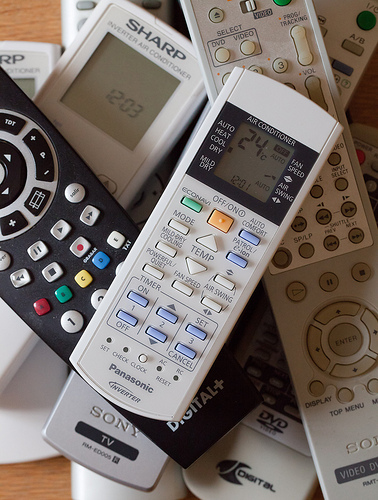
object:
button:
[355, 10, 376, 29]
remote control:
[311, 1, 376, 109]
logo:
[86, 405, 143, 441]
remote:
[41, 369, 170, 493]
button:
[239, 228, 260, 244]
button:
[223, 251, 248, 267]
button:
[33, 297, 52, 316]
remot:
[0, 66, 263, 471]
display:
[186, 100, 321, 228]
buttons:
[0, 106, 55, 243]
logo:
[256, 409, 289, 436]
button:
[291, 25, 313, 65]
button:
[179, 194, 197, 207]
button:
[209, 208, 235, 233]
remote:
[182, 295, 318, 500]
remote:
[0, 0, 210, 391]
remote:
[68, 62, 347, 421]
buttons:
[274, 56, 288, 73]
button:
[175, 342, 197, 360]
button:
[183, 320, 210, 339]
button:
[157, 307, 178, 324]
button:
[115, 309, 138, 327]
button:
[142, 324, 170, 341]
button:
[240, 39, 256, 55]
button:
[213, 46, 230, 62]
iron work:
[68, 64, 346, 423]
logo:
[125, 18, 187, 63]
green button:
[55, 284, 73, 303]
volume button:
[304, 73, 330, 113]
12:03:
[105, 88, 144, 118]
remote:
[180, 0, 378, 500]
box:
[70, 64, 345, 423]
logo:
[108, 360, 154, 404]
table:
[0, 463, 62, 496]